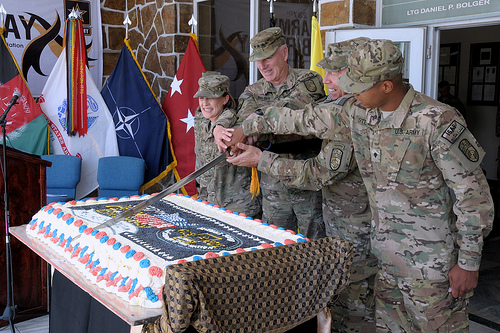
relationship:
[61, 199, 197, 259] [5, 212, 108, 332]
cake on table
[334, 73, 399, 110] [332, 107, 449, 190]
man in uniform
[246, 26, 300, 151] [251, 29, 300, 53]
soldier wearing hat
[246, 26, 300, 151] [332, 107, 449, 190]
soldier in uniform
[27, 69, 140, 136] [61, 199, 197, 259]
flags by cake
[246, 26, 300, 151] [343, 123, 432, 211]
soldier uniform green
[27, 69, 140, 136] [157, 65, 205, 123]
flags have stars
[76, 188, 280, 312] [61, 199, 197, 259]
large rectangular cake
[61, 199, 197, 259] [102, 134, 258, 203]
cake cut sword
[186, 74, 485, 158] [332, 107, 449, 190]
men in uniform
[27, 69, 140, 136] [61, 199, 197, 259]
flags behind cake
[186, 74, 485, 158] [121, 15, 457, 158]
people in daytime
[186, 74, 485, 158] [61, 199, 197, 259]
four people cake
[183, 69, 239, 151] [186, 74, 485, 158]
woman with men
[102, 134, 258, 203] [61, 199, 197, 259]
sword cuts cake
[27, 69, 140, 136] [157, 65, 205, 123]
flags with stars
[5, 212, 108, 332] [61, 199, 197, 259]
table under cake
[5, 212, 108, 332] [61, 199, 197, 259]
table with cake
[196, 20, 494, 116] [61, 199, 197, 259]
four uniform cake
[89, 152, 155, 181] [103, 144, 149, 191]
chair colored blue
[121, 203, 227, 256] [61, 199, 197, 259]
military med cake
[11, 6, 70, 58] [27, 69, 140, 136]
sign behind flags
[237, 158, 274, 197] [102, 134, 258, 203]
tassel from sword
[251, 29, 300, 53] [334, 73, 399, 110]
hat on man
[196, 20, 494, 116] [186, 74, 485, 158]
four military men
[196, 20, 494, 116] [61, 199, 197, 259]
four men cske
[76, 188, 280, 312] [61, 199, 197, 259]
large cut cake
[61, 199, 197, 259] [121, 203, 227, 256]
cake with military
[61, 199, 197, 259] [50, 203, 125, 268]
cake with white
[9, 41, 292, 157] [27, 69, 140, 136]
row of flags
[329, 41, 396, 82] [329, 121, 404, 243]
cap with camoflauge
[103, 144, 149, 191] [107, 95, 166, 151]
blue flag emblem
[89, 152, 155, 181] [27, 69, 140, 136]
chair front flags